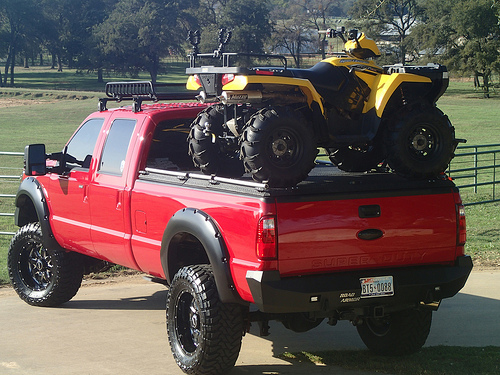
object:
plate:
[357, 275, 396, 300]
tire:
[377, 98, 463, 182]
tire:
[324, 141, 389, 176]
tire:
[236, 104, 321, 190]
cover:
[132, 208, 146, 233]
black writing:
[359, 280, 394, 295]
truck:
[7, 80, 476, 375]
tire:
[186, 96, 247, 181]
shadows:
[61, 289, 499, 374]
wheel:
[7, 219, 88, 309]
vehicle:
[184, 28, 465, 191]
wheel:
[163, 264, 246, 374]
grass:
[0, 67, 499, 290]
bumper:
[243, 255, 473, 315]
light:
[262, 218, 276, 229]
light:
[456, 207, 466, 216]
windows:
[59, 116, 105, 174]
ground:
[2, 68, 499, 374]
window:
[95, 116, 137, 178]